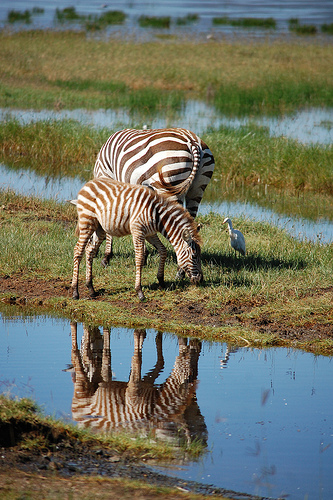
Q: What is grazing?
A: Zebras.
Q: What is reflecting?
A: The zebras.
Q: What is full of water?
A: The Delta.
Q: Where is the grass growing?
A: By the river.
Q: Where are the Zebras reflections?
A: In the water.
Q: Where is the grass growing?
A: Through the water.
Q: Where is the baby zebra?
A: Near the water.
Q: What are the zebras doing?
A: Grazing.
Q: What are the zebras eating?
A: Grass.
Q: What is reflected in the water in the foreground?
A: Zebra.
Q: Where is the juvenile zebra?
A: In the reflection of the water.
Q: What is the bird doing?
A: Standing next to the zebras.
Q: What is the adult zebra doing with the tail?
A: Swingin the tail.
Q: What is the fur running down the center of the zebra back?
A: Mane.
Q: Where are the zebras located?
A: Green field and marsh.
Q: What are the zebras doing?
A: Grazing.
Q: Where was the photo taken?
A: African savannah.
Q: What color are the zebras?
A: White and brown.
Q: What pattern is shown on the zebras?
A: Stripes.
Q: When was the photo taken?
A: Daytime.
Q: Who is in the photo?
A: No one.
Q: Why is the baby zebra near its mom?
A: To stay safe.